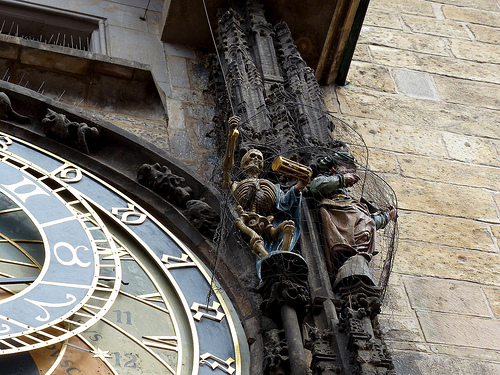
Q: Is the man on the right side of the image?
A: Yes, the man is on the right of the image.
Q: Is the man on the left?
A: No, the man is on the right of the image.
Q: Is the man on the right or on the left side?
A: The man is on the right of the image.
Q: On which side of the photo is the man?
A: The man is on the right of the image.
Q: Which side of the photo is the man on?
A: The man is on the right of the image.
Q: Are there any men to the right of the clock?
A: Yes, there is a man to the right of the clock.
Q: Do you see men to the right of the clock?
A: Yes, there is a man to the right of the clock.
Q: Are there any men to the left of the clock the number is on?
A: No, the man is to the right of the clock.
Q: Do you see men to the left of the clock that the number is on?
A: No, the man is to the right of the clock.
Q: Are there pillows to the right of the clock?
A: No, there is a man to the right of the clock.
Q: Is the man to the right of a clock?
A: Yes, the man is to the right of a clock.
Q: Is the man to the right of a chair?
A: No, the man is to the right of a clock.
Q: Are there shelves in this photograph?
A: No, there are no shelves.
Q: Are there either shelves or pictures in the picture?
A: No, there are no shelves or pictures.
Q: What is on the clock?
A: The number is on the clock.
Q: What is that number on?
A: The number is on the clock.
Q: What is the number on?
A: The number is on the clock.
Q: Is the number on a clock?
A: Yes, the number is on a clock.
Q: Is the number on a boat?
A: No, the number is on a clock.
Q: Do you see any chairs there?
A: No, there are no chairs.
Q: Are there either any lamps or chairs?
A: No, there are no chairs or lamps.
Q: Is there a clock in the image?
A: Yes, there is a clock.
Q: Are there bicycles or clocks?
A: Yes, there is a clock.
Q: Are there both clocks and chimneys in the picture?
A: No, there is a clock but no chimneys.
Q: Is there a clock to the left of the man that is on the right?
A: Yes, there is a clock to the left of the man.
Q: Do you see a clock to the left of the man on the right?
A: Yes, there is a clock to the left of the man.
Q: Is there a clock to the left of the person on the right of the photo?
A: Yes, there is a clock to the left of the man.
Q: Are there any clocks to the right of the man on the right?
A: No, the clock is to the left of the man.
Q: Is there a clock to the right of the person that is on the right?
A: No, the clock is to the left of the man.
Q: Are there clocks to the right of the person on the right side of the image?
A: No, the clock is to the left of the man.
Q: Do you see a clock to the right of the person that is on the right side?
A: No, the clock is to the left of the man.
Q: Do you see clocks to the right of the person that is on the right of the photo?
A: No, the clock is to the left of the man.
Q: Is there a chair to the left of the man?
A: No, there is a clock to the left of the man.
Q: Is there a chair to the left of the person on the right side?
A: No, there is a clock to the left of the man.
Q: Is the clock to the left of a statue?
A: No, the clock is to the left of a man.